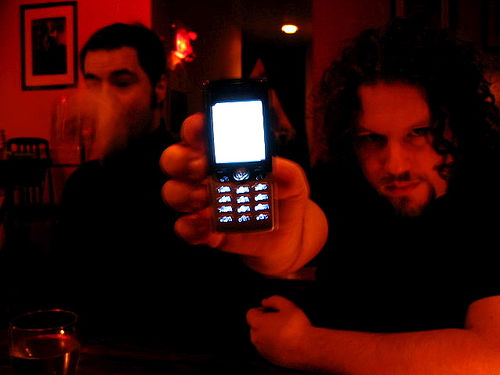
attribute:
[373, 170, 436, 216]
facial hair — goatee, black, groomed well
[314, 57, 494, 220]
hair — long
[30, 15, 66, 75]
photograph — framed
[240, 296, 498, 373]
arm — oversaturated, red, colored, bare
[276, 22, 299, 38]
light — illuminated, round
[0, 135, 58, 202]
chair — wooden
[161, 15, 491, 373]
male — long haired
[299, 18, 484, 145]
hair — black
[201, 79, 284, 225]
phone — rectangular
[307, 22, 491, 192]
hair — black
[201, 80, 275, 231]
smartphone — illuminated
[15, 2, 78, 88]
frame — black